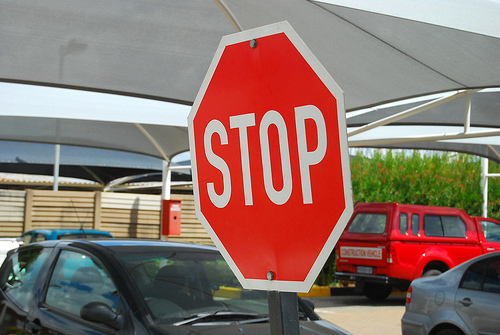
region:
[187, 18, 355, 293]
a red stop sign with a white border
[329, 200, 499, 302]
a red truck with a red camper shell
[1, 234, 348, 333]
a parked black car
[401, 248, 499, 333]
a parked silver car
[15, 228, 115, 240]
top of a blue vehicle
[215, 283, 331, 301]
a yellow curb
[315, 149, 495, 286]
hedges with green and red on it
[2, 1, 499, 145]
a gray colored roof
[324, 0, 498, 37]
a blue colored sky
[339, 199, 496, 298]
a Chevrolet pick-up truck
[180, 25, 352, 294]
Stop sign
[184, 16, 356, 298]
Road stop sign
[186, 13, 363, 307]
Road stop sign with a red background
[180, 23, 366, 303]
Road stop sign with white letters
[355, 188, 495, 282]
Part of a red truck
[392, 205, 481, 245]
Back windows on a truck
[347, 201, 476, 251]
Back windows on a red truck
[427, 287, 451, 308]
The opening of a gas tank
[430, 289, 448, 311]
The opening of a gas tank on a car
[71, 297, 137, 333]
Car side mirror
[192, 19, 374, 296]
red and white stop sign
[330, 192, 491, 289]
red truck parked on street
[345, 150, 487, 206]
green bush with red flowers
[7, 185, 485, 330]
cars parked in a parking lot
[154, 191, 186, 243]
red box attached to poll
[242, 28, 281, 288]
two screws on stop sign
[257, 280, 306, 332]
black metal pole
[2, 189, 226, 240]
brown wooden fence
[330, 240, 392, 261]
white sign on back of truck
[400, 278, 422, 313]
red brake light on silver car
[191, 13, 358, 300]
Red and white stop sign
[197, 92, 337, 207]
White lettering on the sign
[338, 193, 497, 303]
Red and white truck parked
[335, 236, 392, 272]
White stripe on back of truck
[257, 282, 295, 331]
Gray pole holding up sign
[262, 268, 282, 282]
Silver bolt on stop sign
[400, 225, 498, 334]
Small gray car in the corner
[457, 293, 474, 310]
Small silver door handle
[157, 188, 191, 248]
Red box on the grey pole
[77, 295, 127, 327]
Black rear view mirror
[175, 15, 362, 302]
The sign is red and white.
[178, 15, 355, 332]
The sign is hanging on a post.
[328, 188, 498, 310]
The truck is red.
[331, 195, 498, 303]
The truck is parked.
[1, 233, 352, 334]
The car is black.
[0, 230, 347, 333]
The car is parked.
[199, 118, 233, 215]
The letter is white.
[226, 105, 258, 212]
The letter is white.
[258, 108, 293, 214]
The letter is white.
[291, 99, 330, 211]
The letter is white.